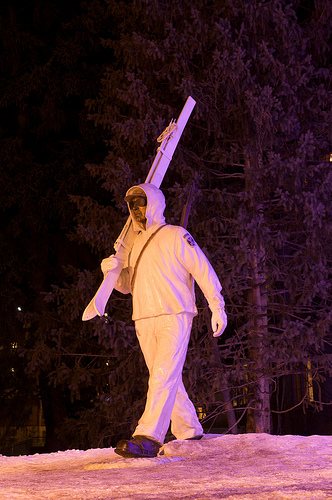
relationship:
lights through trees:
[17, 306, 22, 312] [209, 2, 331, 433]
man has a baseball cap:
[101, 183, 229, 458] [123, 189, 146, 200]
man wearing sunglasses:
[101, 183, 229, 458] [128, 197, 147, 208]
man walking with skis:
[101, 183, 229, 458] [82, 95, 197, 321]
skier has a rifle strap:
[101, 183, 229, 458] [130, 186, 199, 295]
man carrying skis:
[101, 183, 229, 458] [82, 95, 197, 321]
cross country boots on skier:
[114, 434, 159, 459] [101, 183, 229, 458]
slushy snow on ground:
[204, 433, 332, 500] [1, 453, 332, 500]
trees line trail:
[209, 2, 331, 433] [0, 435, 330, 499]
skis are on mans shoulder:
[82, 95, 197, 321] [80, 226, 142, 322]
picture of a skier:
[2, 1, 332, 500] [101, 183, 229, 458]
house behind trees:
[200, 354, 331, 433] [209, 2, 331, 433]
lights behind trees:
[17, 306, 22, 312] [209, 2, 331, 433]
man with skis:
[101, 183, 229, 458] [82, 95, 197, 321]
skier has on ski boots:
[101, 183, 229, 458] [114, 434, 159, 459]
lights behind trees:
[17, 306, 22, 312] [0, 0, 97, 449]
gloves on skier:
[208, 309, 229, 337] [101, 183, 229, 458]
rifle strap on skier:
[130, 186, 199, 295] [101, 183, 229, 458]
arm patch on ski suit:
[181, 233, 197, 249] [101, 183, 229, 458]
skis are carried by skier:
[82, 95, 197, 321] [101, 183, 229, 458]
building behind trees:
[200, 354, 331, 433] [0, 0, 97, 449]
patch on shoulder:
[181, 233, 197, 249] [172, 223, 204, 261]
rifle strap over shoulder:
[130, 186, 199, 295] [172, 223, 204, 261]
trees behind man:
[209, 2, 331, 433] [101, 183, 226, 458]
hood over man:
[123, 183, 167, 232] [101, 183, 226, 458]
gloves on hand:
[208, 309, 229, 337] [211, 309, 226, 337]